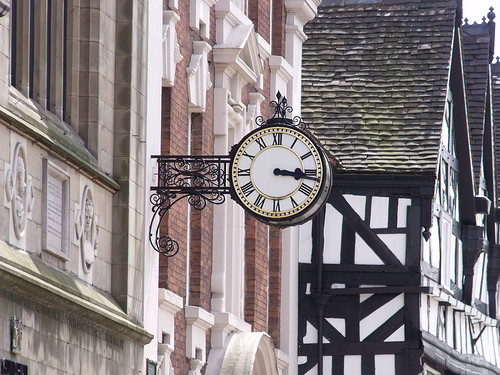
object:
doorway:
[249, 353, 271, 374]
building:
[299, 1, 500, 375]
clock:
[230, 123, 333, 227]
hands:
[273, 168, 320, 181]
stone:
[0, 244, 153, 348]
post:
[150, 154, 233, 257]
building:
[0, 1, 154, 374]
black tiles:
[1, 359, 28, 374]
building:
[146, 0, 312, 374]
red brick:
[167, 282, 186, 297]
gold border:
[319, 161, 323, 187]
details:
[186, 41, 213, 113]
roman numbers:
[255, 137, 267, 150]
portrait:
[84, 199, 95, 266]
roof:
[301, 0, 476, 223]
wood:
[407, 205, 421, 266]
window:
[215, 112, 245, 315]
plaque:
[43, 157, 72, 260]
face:
[85, 208, 93, 231]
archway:
[204, 331, 276, 374]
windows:
[10, 0, 70, 118]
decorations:
[256, 90, 306, 129]